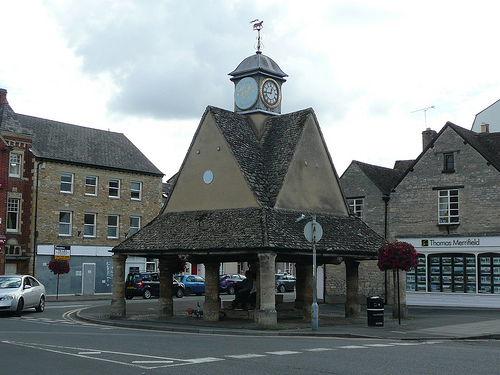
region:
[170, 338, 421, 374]
white lines painted on a road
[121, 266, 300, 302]
cars parked next to a road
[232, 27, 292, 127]
a clock on top of a pavillion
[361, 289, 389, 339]
a black garbage can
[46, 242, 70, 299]
a flower pot on a post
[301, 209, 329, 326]
a road sign on a pole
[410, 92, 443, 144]
a antenna on top of a building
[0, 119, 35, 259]
a red brick building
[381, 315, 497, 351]
a concrete sidewalk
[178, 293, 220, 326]
a bike laying on its side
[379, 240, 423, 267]
red leaves on the young tree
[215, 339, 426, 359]
several white markings on the street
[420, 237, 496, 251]
the sign on the building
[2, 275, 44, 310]
a white car turning the corner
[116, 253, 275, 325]
several columns holding up building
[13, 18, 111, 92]
several clouds in the sky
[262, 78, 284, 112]
a circular clock on the tower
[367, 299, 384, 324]
a black trash can near sidewalk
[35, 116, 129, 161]
the roof on the brick building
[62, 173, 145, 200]
several windows in the brick building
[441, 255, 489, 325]
display window of shop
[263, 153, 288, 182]
brown shingles on roof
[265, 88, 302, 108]
clock face atop a building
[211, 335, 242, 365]
white lines on street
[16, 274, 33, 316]
silver small sedan on street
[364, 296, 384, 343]
black trash bin by road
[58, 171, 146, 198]
4 windows in brown building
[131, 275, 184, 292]
small black car on road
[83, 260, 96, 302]
gray door in brown building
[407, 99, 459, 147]
antennae atop a roof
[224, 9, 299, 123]
a small clock tower.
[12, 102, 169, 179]
A multi story building roof top.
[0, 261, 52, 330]
A car making a turn.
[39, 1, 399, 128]
a large gray cloud.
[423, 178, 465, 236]
a window on a house.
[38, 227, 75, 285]
a sign on a building.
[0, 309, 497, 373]
a paved road.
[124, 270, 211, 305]
A van in front of a building.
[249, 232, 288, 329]
a pillar on a building.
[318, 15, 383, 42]
a section of clear sky.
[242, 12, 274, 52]
weathervane on top of a building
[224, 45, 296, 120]
a clock in the middle of a roundabout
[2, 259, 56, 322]
silver car rounding the road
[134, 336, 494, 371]
a cross walk in the middle of the pavement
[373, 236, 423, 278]
a flowering bush in the center of town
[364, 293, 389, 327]
trash receptical near the corner of a street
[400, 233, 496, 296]
a storefront with photos in the windows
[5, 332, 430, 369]
road markings painted in white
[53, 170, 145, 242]
windows in a building that face the road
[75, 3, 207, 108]
grey rain clouds moving in